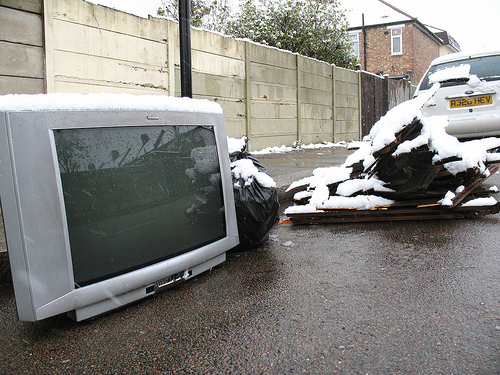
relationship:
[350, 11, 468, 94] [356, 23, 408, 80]
house with wall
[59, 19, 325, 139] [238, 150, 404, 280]
fence by pavement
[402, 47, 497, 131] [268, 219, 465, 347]
car on pavement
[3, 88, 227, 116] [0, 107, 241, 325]
snow on television set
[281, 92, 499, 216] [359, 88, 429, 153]
boxes covered in snow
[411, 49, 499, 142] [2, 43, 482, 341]
car behind trash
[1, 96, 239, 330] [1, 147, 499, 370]
television set on ground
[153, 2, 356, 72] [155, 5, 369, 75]
leaves on a tree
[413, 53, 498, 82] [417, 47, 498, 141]
back window of a car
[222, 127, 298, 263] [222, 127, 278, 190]
trash bag with snow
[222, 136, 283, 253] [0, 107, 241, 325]
trash bag next to television set